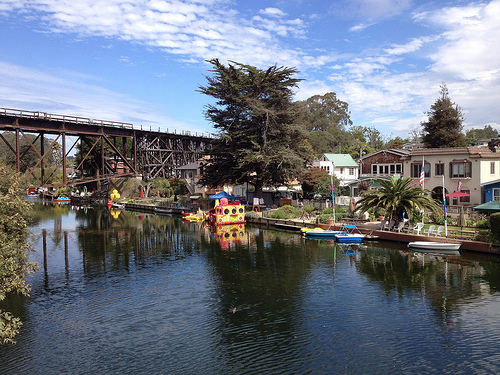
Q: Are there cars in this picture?
A: No, there are no cars.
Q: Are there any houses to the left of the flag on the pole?
A: Yes, there is a house to the left of the flag.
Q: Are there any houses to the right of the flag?
A: No, the house is to the left of the flag.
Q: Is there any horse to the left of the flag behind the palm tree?
A: No, there is a house to the left of the flag.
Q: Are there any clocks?
A: No, there are no clocks.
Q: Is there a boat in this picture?
A: Yes, there is a boat.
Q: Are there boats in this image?
A: Yes, there is a boat.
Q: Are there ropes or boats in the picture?
A: Yes, there is a boat.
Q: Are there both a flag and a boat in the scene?
A: Yes, there are both a boat and a flag.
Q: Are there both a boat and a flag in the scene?
A: Yes, there are both a boat and a flag.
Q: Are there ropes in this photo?
A: No, there are no ropes.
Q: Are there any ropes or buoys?
A: No, there are no ropes or buoys.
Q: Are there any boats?
A: Yes, there is a boat.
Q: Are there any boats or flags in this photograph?
A: Yes, there is a boat.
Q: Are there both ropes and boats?
A: No, there is a boat but no ropes.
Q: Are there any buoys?
A: No, there are no buoys.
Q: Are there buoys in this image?
A: No, there are no buoys.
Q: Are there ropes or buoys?
A: No, there are no buoys or ropes.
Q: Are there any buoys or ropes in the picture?
A: No, there are no buoys or ropes.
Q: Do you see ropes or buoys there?
A: No, there are no buoys or ropes.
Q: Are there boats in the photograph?
A: Yes, there is a boat.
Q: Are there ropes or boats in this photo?
A: Yes, there is a boat.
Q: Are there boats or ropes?
A: Yes, there is a boat.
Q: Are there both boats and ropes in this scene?
A: No, there is a boat but no ropes.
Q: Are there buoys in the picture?
A: No, there are no buoys.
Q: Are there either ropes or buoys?
A: No, there are no buoys or ropes.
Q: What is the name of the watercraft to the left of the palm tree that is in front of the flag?
A: The watercraft is a boat.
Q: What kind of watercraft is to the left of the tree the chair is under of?
A: The watercraft is a boat.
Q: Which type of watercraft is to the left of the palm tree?
A: The watercraft is a boat.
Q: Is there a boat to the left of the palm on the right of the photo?
A: Yes, there is a boat to the left of the palm tree.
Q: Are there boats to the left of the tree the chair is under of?
A: Yes, there is a boat to the left of the palm tree.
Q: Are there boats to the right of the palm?
A: No, the boat is to the left of the palm.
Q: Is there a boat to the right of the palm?
A: No, the boat is to the left of the palm.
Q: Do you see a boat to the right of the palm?
A: No, the boat is to the left of the palm.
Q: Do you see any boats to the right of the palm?
A: No, the boat is to the left of the palm.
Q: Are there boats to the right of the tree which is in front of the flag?
A: No, the boat is to the left of the palm.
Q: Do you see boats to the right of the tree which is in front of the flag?
A: No, the boat is to the left of the palm.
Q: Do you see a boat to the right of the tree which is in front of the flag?
A: No, the boat is to the left of the palm.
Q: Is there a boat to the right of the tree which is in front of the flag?
A: No, the boat is to the left of the palm.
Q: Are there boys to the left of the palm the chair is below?
A: No, there is a boat to the left of the palm tree.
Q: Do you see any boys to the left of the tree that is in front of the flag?
A: No, there is a boat to the left of the palm tree.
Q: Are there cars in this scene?
A: No, there are no cars.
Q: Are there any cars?
A: No, there are no cars.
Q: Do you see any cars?
A: No, there are no cars.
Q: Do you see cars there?
A: No, there are no cars.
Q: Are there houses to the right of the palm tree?
A: Yes, there is a house to the right of the palm tree.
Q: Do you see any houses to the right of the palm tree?
A: Yes, there is a house to the right of the palm tree.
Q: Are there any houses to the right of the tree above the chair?
A: Yes, there is a house to the right of the palm tree.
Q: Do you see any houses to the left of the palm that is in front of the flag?
A: No, the house is to the right of the palm tree.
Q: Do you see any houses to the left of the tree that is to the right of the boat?
A: No, the house is to the right of the palm tree.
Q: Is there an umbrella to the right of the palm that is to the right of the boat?
A: No, there is a house to the right of the palm.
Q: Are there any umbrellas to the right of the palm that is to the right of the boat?
A: No, there is a house to the right of the palm.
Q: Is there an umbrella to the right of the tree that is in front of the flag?
A: No, there is a house to the right of the palm.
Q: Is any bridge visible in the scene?
A: Yes, there is a bridge.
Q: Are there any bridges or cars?
A: Yes, there is a bridge.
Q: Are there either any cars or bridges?
A: Yes, there is a bridge.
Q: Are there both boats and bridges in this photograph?
A: Yes, there are both a bridge and a boat.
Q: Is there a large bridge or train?
A: Yes, there is a large bridge.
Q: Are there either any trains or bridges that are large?
A: Yes, the bridge is large.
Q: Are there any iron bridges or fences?
A: Yes, there is an iron bridge.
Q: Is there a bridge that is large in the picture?
A: Yes, there is a large bridge.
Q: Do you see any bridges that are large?
A: Yes, there is a bridge that is large.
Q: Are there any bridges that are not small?
A: Yes, there is a large bridge.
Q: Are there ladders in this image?
A: No, there are no ladders.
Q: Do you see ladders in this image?
A: No, there are no ladders.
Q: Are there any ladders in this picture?
A: No, there are no ladders.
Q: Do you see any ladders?
A: No, there are no ladders.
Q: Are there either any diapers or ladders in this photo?
A: No, there are no ladders or diapers.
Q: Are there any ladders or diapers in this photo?
A: No, there are no ladders or diapers.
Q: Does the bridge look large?
A: Yes, the bridge is large.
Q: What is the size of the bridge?
A: The bridge is large.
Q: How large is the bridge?
A: The bridge is large.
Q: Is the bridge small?
A: No, the bridge is large.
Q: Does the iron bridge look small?
A: No, the bridge is large.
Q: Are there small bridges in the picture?
A: No, there is a bridge but it is large.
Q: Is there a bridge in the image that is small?
A: No, there is a bridge but it is large.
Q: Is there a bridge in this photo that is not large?
A: No, there is a bridge but it is large.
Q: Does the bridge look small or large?
A: The bridge is large.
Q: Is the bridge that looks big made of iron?
A: Yes, the bridge is made of iron.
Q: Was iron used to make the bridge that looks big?
A: Yes, the bridge is made of iron.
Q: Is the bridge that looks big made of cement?
A: No, the bridge is made of iron.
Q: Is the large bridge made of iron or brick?
A: The bridge is made of iron.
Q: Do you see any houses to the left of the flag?
A: Yes, there is a house to the left of the flag.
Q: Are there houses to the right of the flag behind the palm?
A: No, the house is to the left of the flag.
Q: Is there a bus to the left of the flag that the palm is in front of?
A: No, there is a house to the left of the flag.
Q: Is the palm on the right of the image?
A: Yes, the palm is on the right of the image.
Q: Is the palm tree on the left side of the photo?
A: No, the palm tree is on the right of the image.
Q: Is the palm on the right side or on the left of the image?
A: The palm is on the right of the image.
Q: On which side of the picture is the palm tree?
A: The palm tree is on the right of the image.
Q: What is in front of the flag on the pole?
A: The palm tree is in front of the flag.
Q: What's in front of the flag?
A: The palm tree is in front of the flag.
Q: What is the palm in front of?
A: The palm is in front of the flag.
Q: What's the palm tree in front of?
A: The palm is in front of the flag.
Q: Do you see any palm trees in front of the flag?
A: Yes, there is a palm tree in front of the flag.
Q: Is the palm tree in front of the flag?
A: Yes, the palm tree is in front of the flag.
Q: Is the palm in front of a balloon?
A: No, the palm is in front of the flag.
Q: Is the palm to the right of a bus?
A: No, the palm is to the right of the boat.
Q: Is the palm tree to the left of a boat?
A: No, the palm tree is to the right of a boat.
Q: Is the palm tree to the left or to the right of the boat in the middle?
A: The palm tree is to the right of the boat.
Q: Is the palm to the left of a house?
A: Yes, the palm is to the left of a house.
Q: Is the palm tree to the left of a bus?
A: No, the palm tree is to the left of a house.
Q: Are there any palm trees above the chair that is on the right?
A: Yes, there is a palm tree above the chair.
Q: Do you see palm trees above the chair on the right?
A: Yes, there is a palm tree above the chair.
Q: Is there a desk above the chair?
A: No, there is a palm tree above the chair.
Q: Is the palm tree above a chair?
A: Yes, the palm tree is above a chair.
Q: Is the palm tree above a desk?
A: No, the palm tree is above a chair.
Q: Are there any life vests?
A: No, there are no life vests.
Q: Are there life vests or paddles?
A: No, there are no life vests or paddles.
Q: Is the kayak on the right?
A: Yes, the kayak is on the right of the image.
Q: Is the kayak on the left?
A: No, the kayak is on the right of the image.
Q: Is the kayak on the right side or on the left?
A: The kayak is on the right of the image.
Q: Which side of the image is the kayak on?
A: The kayak is on the right of the image.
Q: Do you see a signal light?
A: No, there are no traffic lights.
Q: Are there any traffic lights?
A: No, there are no traffic lights.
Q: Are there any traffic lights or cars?
A: No, there are no traffic lights or cars.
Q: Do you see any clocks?
A: No, there are no clocks.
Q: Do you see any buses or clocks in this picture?
A: No, there are no clocks or buses.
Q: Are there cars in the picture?
A: No, there are no cars.